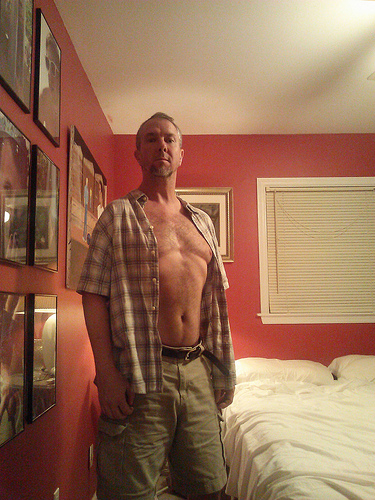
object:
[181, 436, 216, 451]
line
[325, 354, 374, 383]
pillow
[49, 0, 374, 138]
ceiling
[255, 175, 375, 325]
windowframe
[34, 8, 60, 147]
picture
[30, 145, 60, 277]
picture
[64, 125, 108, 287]
frame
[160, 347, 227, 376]
belt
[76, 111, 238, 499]
man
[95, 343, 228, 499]
shorts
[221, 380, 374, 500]
bed sheets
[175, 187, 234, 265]
frame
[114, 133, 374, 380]
wall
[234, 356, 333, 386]
pillow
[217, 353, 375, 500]
bed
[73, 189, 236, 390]
shirt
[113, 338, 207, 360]
waist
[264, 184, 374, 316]
blinds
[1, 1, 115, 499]
wall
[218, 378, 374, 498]
part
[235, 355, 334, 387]
part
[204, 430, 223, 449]
part